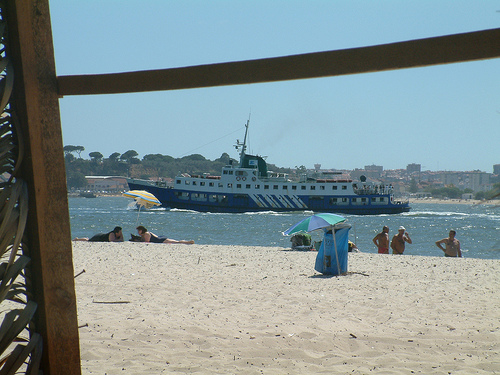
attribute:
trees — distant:
[61, 142, 230, 173]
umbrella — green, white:
[281, 211, 347, 276]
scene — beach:
[59, 167, 466, 372]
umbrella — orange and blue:
[128, 184, 161, 209]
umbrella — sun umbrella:
[284, 211, 346, 236]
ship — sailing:
[125, 112, 412, 217]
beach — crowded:
[72, 238, 497, 373]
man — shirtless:
[435, 232, 464, 255]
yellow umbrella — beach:
[122, 182, 164, 216]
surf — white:
[377, 206, 498, 226]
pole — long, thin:
[353, 222, 360, 252]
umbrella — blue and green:
[280, 203, 348, 278]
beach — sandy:
[0, 231, 496, 373]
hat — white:
[391, 226, 417, 255]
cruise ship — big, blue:
[119, 139, 412, 219]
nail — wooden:
[75, 267, 86, 278]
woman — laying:
[132, 225, 196, 246]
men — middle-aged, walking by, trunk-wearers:
[359, 213, 468, 263]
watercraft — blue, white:
[128, 111, 408, 213]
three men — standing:
[371, 220, 472, 263]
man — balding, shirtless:
[373, 224, 392, 256]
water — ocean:
[66, 191, 498, 262]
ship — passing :
[162, 144, 419, 201]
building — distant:
[403, 160, 419, 203]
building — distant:
[431, 167, 451, 186]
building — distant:
[458, 168, 470, 188]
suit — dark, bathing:
[150, 229, 169, 243]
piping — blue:
[130, 191, 162, 207]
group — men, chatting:
[371, 219, 469, 260]